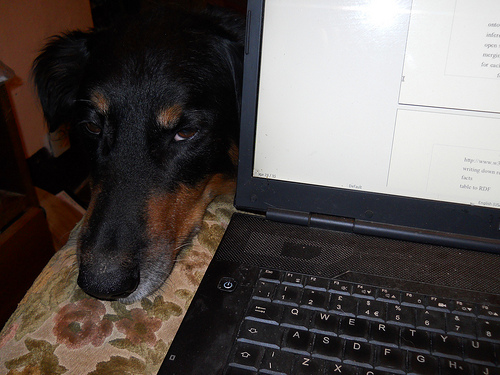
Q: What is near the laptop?
A: Dog.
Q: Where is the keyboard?
A: On the laptop.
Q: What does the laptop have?
A: Screen.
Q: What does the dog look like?
A: Bored.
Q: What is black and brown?
A: The dog.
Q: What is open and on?
A: Laptop.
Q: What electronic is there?
A: Laptop.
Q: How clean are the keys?
A: Dirty.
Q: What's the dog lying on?
A: Mat.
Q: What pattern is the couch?
A: Floral.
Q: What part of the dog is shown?
A: Head.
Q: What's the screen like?
A: Powered on.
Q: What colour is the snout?
A: Black.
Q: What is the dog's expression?
A: Sleepy.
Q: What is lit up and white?
A: Monitor.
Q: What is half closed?
A: Eyes.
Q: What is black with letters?
A: Keyboard.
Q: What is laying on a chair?
A: Dog head.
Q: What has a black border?
A: Screen.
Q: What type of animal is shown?
A: A dog.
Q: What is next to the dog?
A: A laptop.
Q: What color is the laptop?
A: Black.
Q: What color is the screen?
A: White.